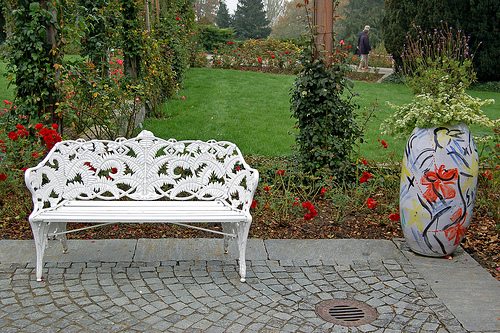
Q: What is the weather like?
A: Sunny.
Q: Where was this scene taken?
A: In the garden.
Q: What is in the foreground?
A: A bench.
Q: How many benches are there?
A: One.